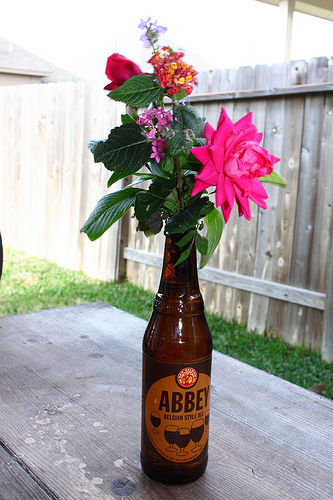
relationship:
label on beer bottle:
[140, 349, 208, 463] [141, 230, 214, 486]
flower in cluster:
[136, 107, 173, 164] [78, 17, 275, 267]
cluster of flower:
[78, 17, 275, 267] [136, 107, 173, 164]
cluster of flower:
[78, 17, 275, 267] [190, 107, 279, 223]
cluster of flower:
[78, 17, 275, 267] [147, 45, 197, 94]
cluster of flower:
[78, 17, 275, 267] [139, 16, 166, 47]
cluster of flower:
[78, 17, 275, 267] [103, 52, 147, 88]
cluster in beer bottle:
[78, 17, 275, 267] [141, 230, 214, 486]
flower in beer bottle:
[136, 107, 173, 164] [141, 230, 214, 486]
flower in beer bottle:
[190, 107, 279, 223] [141, 230, 214, 486]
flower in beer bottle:
[147, 45, 197, 94] [141, 230, 214, 486]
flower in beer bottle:
[139, 16, 166, 47] [141, 230, 214, 486]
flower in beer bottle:
[103, 52, 147, 88] [141, 230, 214, 486]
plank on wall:
[15, 78, 64, 250] [5, 50, 70, 218]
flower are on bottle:
[147, 47, 199, 95] [136, 217, 216, 490]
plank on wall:
[182, 59, 306, 105] [238, 228, 294, 335]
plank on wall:
[121, 246, 329, 310] [0, 56, 332, 363]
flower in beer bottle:
[135, 105, 170, 155] [124, 225, 236, 485]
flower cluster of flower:
[76, 10, 287, 252] [135, 105, 170, 155]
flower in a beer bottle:
[136, 107, 173, 164] [140, 219, 211, 487]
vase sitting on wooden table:
[136, 221, 213, 491] [0, 299, 331, 498]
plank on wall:
[247, 87, 309, 243] [190, 46, 314, 346]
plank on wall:
[24, 83, 54, 260] [0, 54, 319, 296]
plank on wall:
[245, 56, 332, 345] [0, 56, 332, 363]